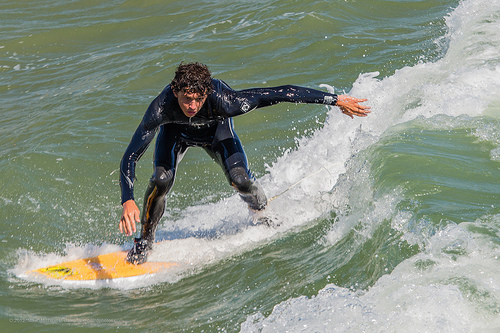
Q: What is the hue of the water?
A: White.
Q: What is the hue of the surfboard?
A: Yellow.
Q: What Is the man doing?
A: Surfing in the ocean.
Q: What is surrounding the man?
A: The water in the ocean.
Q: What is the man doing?
A: Surfing.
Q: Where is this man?
A: The ocean.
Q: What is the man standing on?
A: A surfboard.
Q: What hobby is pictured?
A: Surfing.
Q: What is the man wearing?
A: A wet suit.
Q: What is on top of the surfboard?
A: A man.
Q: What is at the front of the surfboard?
A: A logo.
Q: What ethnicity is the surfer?
A: White.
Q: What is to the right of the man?
A: A wave.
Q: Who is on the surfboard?
A: A surfer.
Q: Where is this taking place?
A: The ocean.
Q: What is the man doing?
A: Surfing.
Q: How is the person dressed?
A: In a wet suit.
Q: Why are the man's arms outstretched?
A: For balancing.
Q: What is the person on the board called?
A: A surfer.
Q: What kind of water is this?
A: Salt water.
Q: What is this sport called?
A: Surfing.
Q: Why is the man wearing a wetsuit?
A: To keep warm.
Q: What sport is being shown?
A: Surfing.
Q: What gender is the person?
A: Male.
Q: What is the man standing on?
A: Surfboard.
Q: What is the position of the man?
A: Crouched.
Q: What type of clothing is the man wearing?
A: Wet suit.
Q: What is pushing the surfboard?
A: Waves.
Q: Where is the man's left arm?
A: Outstretched beside of him.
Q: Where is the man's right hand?
A: Hanging down above the board.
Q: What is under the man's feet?
A: Surfboard.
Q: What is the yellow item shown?
A: Surfboard.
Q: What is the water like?
A: Wavy.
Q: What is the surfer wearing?
A: Wetsuit.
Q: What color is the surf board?
A: Yellow.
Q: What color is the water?
A: Green.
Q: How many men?
A: One.